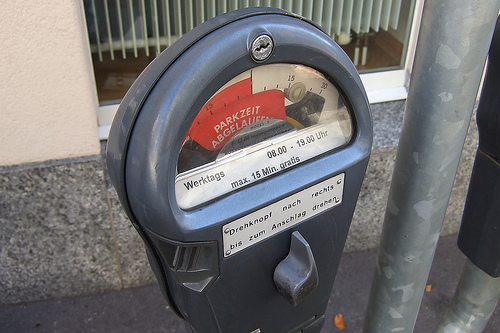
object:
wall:
[0, 156, 141, 300]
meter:
[105, 5, 372, 333]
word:
[183, 171, 225, 190]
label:
[182, 130, 329, 191]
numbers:
[288, 75, 295, 81]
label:
[223, 172, 345, 259]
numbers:
[266, 151, 273, 159]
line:
[197, 121, 200, 124]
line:
[210, 110, 213, 115]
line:
[250, 69, 253, 95]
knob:
[274, 230, 320, 307]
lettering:
[212, 106, 273, 150]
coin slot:
[173, 245, 202, 273]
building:
[0, 0, 495, 333]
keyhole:
[251, 34, 273, 60]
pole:
[361, 0, 496, 333]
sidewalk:
[0, 234, 500, 332]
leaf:
[334, 313, 347, 331]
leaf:
[425, 282, 432, 292]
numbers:
[251, 171, 261, 180]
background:
[173, 71, 347, 179]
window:
[82, 0, 415, 106]